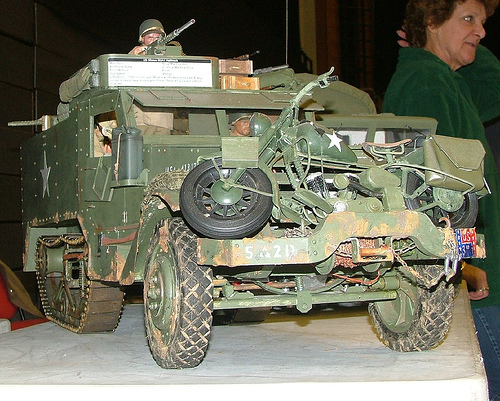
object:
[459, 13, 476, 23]
eye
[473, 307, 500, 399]
jeans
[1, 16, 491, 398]
display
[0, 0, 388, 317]
wall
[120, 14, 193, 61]
gunner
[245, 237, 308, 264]
number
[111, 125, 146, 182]
fuel can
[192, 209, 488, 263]
bumper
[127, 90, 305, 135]
windshield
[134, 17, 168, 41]
cap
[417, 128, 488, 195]
saddle bag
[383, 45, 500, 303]
shirt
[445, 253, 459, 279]
bracelet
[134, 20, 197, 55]
gun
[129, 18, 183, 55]
soldier figurine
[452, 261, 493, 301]
hand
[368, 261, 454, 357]
machine wheel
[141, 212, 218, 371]
front wheels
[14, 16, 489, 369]
army tank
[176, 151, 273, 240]
wheel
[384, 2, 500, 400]
caucasian woman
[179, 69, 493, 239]
bike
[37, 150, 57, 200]
white star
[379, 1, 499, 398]
person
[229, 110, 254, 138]
man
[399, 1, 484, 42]
hair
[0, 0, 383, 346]
wood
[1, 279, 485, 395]
road